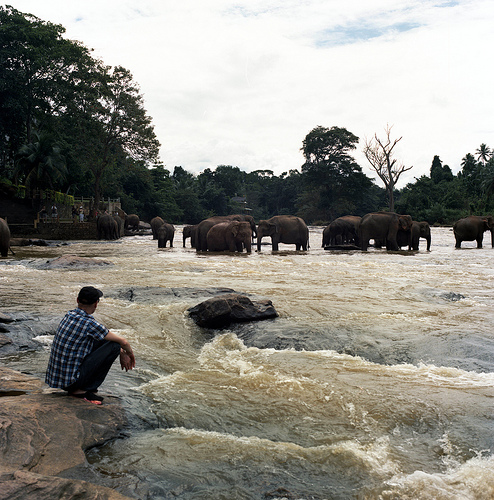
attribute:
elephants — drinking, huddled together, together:
[88, 208, 493, 255]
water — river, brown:
[3, 229, 493, 497]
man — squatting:
[47, 286, 135, 405]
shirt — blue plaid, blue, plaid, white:
[43, 307, 107, 387]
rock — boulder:
[184, 287, 278, 331]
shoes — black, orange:
[76, 389, 106, 410]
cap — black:
[77, 283, 104, 304]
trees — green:
[148, 125, 493, 223]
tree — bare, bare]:
[364, 128, 416, 212]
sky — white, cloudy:
[10, 2, 493, 165]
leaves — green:
[5, 8, 159, 182]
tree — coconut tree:
[19, 129, 77, 221]